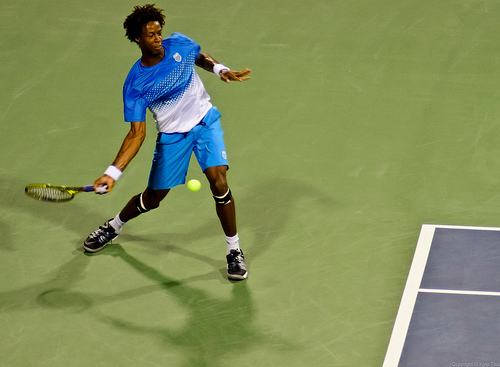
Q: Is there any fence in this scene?
A: No, there are no fences.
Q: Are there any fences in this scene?
A: No, there are no fences.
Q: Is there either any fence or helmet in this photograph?
A: No, there are no fences or helmets.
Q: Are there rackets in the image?
A: Yes, there is a racket.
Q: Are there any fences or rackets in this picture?
A: Yes, there is a racket.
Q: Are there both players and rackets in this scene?
A: Yes, there are both a racket and a player.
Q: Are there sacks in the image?
A: No, there are no sacks.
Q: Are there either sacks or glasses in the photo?
A: No, there are no sacks or glasses.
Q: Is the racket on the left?
A: Yes, the racket is on the left of the image.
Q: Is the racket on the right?
A: No, the racket is on the left of the image.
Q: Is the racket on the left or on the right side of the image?
A: The racket is on the left of the image.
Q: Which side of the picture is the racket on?
A: The racket is on the left of the image.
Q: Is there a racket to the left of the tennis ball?
A: Yes, there is a racket to the left of the tennis ball.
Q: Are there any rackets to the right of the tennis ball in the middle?
A: No, the racket is to the left of the tennis ball.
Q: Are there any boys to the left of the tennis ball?
A: No, there is a racket to the left of the tennis ball.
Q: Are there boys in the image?
A: No, there are no boys.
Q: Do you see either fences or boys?
A: No, there are no boys or fences.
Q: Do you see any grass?
A: Yes, there is grass.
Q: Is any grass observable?
A: Yes, there is grass.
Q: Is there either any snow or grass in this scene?
A: Yes, there is grass.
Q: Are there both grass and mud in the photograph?
A: No, there is grass but no mud.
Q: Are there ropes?
A: No, there are no ropes.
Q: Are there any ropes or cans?
A: No, there are no ropes or cans.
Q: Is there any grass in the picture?
A: Yes, there is grass.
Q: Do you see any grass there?
A: Yes, there is grass.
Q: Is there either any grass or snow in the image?
A: Yes, there is grass.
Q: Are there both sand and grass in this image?
A: No, there is grass but no sand.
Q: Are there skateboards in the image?
A: No, there are no skateboards.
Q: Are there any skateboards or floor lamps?
A: No, there are no skateboards or floor lamps.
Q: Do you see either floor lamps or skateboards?
A: No, there are no skateboards or floor lamps.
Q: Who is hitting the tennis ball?
A: The player is hitting the tennis ball.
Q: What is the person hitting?
A: The player is hitting the tennis ball.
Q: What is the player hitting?
A: The player is hitting the tennis ball.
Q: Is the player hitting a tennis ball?
A: Yes, the player is hitting a tennis ball.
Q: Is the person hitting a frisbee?
A: No, the player is hitting a tennis ball.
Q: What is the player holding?
A: The player is holding the tennis racket.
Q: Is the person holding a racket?
A: Yes, the player is holding a racket.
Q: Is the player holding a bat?
A: No, the player is holding a racket.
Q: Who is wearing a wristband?
A: The player is wearing a wristband.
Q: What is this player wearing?
A: The player is wearing a wristband.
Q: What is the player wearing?
A: The player is wearing a wristband.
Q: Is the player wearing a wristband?
A: Yes, the player is wearing a wristband.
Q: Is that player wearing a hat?
A: No, the player is wearing a wristband.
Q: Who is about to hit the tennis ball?
A: The player is about to hit the tennis ball.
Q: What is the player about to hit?
A: The player is about to hit the tennis ball.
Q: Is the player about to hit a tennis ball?
A: Yes, the player is about to hit a tennis ball.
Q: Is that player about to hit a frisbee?
A: No, the player is about to hit a tennis ball.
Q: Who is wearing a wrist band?
A: The player is wearing a wrist band.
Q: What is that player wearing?
A: The player is wearing a wristband.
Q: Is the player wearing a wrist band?
A: Yes, the player is wearing a wrist band.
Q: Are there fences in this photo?
A: No, there are no fences.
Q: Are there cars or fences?
A: No, there are no fences or cars.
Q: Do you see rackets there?
A: Yes, there is a racket.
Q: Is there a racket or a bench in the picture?
A: Yes, there is a racket.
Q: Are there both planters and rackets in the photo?
A: No, there is a racket but no planters.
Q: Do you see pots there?
A: No, there are no pots.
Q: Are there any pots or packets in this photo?
A: No, there are no pots or packets.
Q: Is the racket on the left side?
A: Yes, the racket is on the left of the image.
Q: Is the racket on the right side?
A: No, the racket is on the left of the image.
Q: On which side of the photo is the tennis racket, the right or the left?
A: The tennis racket is on the left of the image.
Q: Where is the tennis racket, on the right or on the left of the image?
A: The tennis racket is on the left of the image.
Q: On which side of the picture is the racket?
A: The racket is on the left of the image.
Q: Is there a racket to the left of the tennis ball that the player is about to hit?
A: Yes, there is a racket to the left of the tennis ball.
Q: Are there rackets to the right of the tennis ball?
A: No, the racket is to the left of the tennis ball.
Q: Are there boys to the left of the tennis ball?
A: No, there is a racket to the left of the tennis ball.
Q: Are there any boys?
A: No, there are no boys.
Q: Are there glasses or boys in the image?
A: No, there are no boys or glasses.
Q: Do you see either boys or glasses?
A: No, there are no boys or glasses.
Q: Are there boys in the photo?
A: No, there are no boys.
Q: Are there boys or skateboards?
A: No, there are no boys or skateboards.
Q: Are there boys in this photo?
A: No, there are no boys.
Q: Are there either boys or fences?
A: No, there are no boys or fences.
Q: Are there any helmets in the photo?
A: No, there are no helmets.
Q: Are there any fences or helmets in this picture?
A: No, there are no helmets or fences.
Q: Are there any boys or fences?
A: No, there are no fences or boys.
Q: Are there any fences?
A: No, there are no fences.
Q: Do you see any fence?
A: No, there are no fences.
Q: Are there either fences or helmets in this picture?
A: No, there are no fences or helmets.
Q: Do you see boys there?
A: No, there are no boys.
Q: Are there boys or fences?
A: No, there are no boys or fences.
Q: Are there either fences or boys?
A: No, there are no boys or fences.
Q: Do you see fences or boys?
A: No, there are no boys or fences.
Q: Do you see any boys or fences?
A: No, there are no boys or fences.